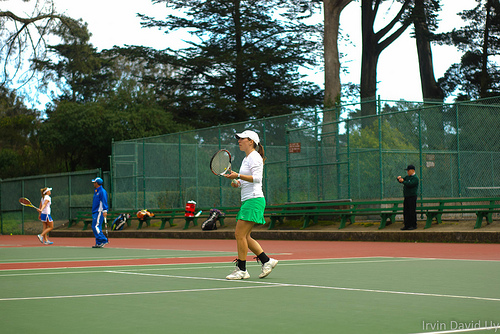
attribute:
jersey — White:
[238, 153, 268, 197]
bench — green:
[73, 192, 493, 232]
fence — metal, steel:
[103, 101, 497, 225]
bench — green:
[263, 181, 405, 233]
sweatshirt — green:
[400, 173, 419, 195]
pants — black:
[402, 199, 416, 229]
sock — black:
[256, 251, 271, 265]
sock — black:
[234, 259, 246, 271]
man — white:
[91, 165, 121, 245]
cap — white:
[238, 130, 260, 150]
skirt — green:
[232, 194, 267, 225]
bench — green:
[70, 192, 498, 218]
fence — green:
[3, 98, 496, 213]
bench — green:
[54, 193, 498, 227]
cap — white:
[233, 127, 263, 140]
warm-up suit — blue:
[91, 189, 109, 242]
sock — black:
[219, 269, 248, 279]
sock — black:
[257, 253, 281, 278]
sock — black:
[234, 260, 246, 270]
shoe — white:
[224, 269, 250, 282]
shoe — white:
[259, 259, 277, 279]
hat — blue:
[93, 175, 105, 183]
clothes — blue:
[90, 191, 111, 238]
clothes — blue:
[88, 182, 115, 242]